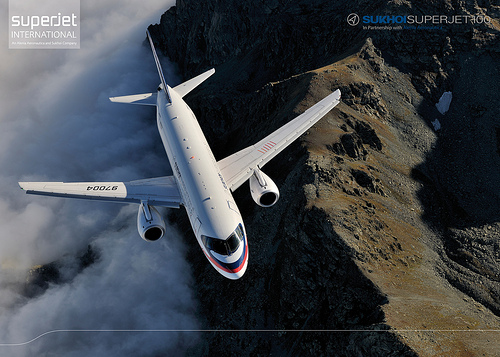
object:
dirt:
[336, 194, 429, 318]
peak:
[304, 47, 404, 353]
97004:
[86, 185, 118, 191]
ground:
[399, 128, 448, 158]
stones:
[417, 80, 459, 145]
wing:
[216, 88, 342, 194]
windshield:
[201, 223, 245, 257]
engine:
[250, 169, 281, 208]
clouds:
[0, 3, 207, 357]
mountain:
[143, 0, 500, 356]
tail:
[140, 26, 175, 95]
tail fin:
[173, 68, 216, 98]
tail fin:
[110, 91, 158, 107]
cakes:
[212, 84, 346, 191]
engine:
[136, 201, 167, 242]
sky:
[1, 1, 206, 356]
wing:
[20, 174, 184, 208]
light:
[190, 156, 195, 160]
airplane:
[17, 28, 342, 282]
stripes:
[257, 140, 279, 154]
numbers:
[86, 185, 119, 191]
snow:
[431, 91, 455, 130]